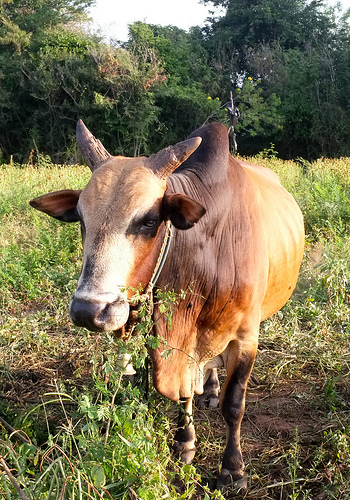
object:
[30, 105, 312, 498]
boar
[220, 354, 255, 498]
legs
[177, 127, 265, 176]
hump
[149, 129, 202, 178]
horns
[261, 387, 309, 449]
patch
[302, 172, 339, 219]
grass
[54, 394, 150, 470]
bushes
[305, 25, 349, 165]
trees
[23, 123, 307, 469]
cow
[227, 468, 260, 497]
hoof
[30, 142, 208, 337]
head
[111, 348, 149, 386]
bell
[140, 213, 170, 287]
rope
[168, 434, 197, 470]
feet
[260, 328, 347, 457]
ground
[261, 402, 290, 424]
dirt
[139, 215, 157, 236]
left eye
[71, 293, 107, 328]
nose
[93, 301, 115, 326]
nostril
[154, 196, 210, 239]
ear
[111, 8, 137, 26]
sky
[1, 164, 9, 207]
weeds